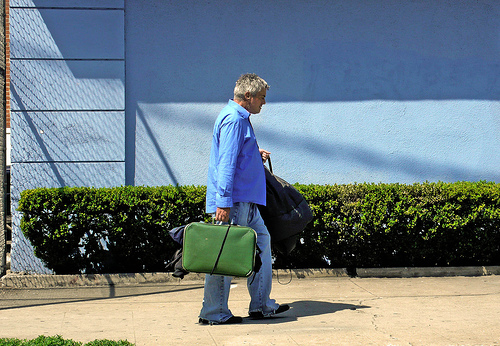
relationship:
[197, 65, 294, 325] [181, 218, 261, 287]
man carrying suitcase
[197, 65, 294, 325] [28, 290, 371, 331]
man on sidewalk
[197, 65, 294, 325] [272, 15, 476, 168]
man near wall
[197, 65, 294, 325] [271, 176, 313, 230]
man with bag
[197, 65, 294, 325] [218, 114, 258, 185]
man wearing shirt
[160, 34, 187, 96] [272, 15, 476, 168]
shadow on wall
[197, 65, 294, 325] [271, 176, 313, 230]
man carrying bag